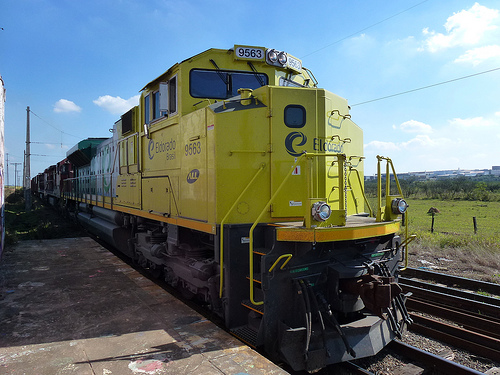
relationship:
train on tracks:
[5, 44, 404, 246] [327, 259, 499, 374]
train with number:
[5, 44, 404, 246] [184, 139, 205, 153]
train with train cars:
[5, 44, 404, 246] [64, 144, 102, 211]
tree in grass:
[417, 172, 499, 204] [383, 179, 493, 239]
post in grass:
[425, 216, 440, 234] [383, 179, 493, 239]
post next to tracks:
[425, 216, 440, 234] [327, 259, 499, 374]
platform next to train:
[15, 238, 281, 374] [5, 44, 404, 246]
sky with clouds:
[3, 1, 499, 176] [421, 4, 499, 67]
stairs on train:
[243, 228, 272, 311] [5, 44, 404, 246]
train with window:
[5, 44, 404, 246] [192, 68, 267, 101]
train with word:
[5, 44, 404, 246] [157, 135, 181, 156]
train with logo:
[5, 44, 404, 246] [285, 130, 310, 160]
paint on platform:
[36, 259, 141, 348] [15, 238, 281, 374]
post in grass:
[468, 214, 481, 233] [383, 179, 493, 239]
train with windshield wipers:
[5, 44, 404, 246] [208, 57, 238, 93]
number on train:
[184, 139, 205, 153] [5, 44, 404, 246]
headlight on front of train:
[308, 204, 331, 226] [5, 44, 404, 246]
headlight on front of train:
[395, 192, 409, 216] [5, 44, 404, 246]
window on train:
[192, 68, 267, 101] [5, 44, 404, 246]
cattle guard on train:
[292, 300, 418, 359] [5, 44, 404, 246]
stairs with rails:
[243, 228, 272, 311] [220, 152, 277, 301]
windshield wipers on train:
[208, 57, 238, 93] [5, 44, 404, 246]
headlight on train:
[308, 204, 331, 226] [5, 44, 404, 246]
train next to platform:
[5, 44, 404, 246] [15, 238, 281, 374]